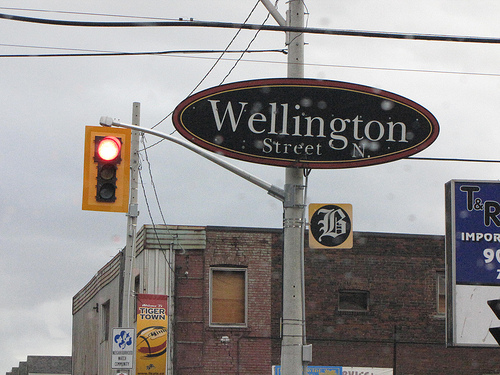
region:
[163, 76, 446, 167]
Large oval black sign with white lettering.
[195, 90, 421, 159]
The words "Wellington Street" on a sign.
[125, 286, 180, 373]
Banner with a picture of a football.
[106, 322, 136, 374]
White and blue "neighborhood watch" sign.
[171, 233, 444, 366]
Large red brick building.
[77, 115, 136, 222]
Traffic light lit up red.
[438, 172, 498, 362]
Blue and white business sign.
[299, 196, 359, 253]
Small yellow and black sign with ornate "B" on it.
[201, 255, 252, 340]
Window.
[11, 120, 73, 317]
Gray sky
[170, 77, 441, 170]
street sign on wellington sign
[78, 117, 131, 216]
traffic signal at an intersection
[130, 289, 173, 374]
yellow and red football banner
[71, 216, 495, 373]
old brick building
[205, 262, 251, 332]
boarded up window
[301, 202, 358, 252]
black and yellow sign with the letter b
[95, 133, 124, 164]
red colored traffic light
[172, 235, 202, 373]
ladder leading to the roof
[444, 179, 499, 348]
blue and white shop sign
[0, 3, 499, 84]
power lines crossing overhead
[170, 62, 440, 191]
oval shaped street sign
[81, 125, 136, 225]
yellow stop light on metal pole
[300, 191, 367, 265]
black and yellow street sign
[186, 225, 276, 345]
window boarded up with plywood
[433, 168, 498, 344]
blue and white advertising sign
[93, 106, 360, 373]
street light on metal pole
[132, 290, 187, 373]
red and yellow advertising sign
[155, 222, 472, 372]
red brick building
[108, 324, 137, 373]
blue and white sign on street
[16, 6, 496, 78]
power lines attached to pole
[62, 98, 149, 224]
yellow stoplight hanging from pole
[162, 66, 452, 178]
oval and black street sign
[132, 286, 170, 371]
red and yellow advertising signage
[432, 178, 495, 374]
blue and white advertising signage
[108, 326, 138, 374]
blue and white street sign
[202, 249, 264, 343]
window boarded up with wood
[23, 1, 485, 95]
power wires running over street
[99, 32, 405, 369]
street light attached to metal pole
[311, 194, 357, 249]
the white letter B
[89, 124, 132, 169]
the red traffic light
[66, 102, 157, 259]
an aerial traffic light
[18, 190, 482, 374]
a brown brick building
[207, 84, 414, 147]
the word Wellington in white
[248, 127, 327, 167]
the white word Street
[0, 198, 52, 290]
the gray sky and clouds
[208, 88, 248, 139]
the white letter W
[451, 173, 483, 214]
the black letter T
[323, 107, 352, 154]
the white letter g